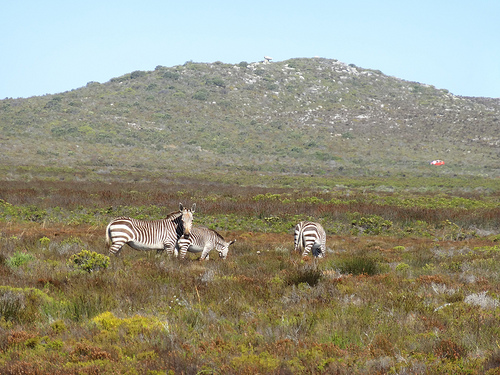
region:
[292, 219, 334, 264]
a zebra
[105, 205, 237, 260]
two zebras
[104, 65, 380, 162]
a mountain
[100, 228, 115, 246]
the zebras tail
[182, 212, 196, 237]
the zebras face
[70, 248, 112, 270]
a green bush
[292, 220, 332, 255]
zebra is black and white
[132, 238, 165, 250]
the zebras belly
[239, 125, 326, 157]
green bushes on the mountain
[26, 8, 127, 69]
a blue sky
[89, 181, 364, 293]
Three zebras in the foreground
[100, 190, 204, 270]
A side view of a zebra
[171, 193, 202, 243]
Zebra is looking at the camera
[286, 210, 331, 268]
A back view of a zebra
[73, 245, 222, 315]
Zebra is standing in the tall grass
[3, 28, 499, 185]
A mountain in the background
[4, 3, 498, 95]
The sky is clear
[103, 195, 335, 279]
Zebra's stripes are black and white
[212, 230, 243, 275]
Zebra is eating grass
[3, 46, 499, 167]
Mountain is covered in plants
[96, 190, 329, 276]
Three zebras in a field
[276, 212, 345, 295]
Back of zebra eating grass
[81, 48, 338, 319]
Picture of zebra taken during the day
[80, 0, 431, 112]
Sky overhead is blue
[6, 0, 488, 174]
No clouds in the sky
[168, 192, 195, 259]
Zebra looking at camera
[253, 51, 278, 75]
A goat on the hill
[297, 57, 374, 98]
Rocks on the hill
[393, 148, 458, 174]
Something red and white in the distance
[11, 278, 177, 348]
Multicolored brush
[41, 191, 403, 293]
zebras grazing in a valley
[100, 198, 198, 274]
the zebra has his head up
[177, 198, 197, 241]
the head of the zebra is white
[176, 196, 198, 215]
the zebra's ears are facing forward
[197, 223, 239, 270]
the zebra has his nose in the grass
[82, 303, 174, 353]
the grass has yellow leaves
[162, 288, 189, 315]
white flowers are in the valley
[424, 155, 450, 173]
an orange vehicle is in the distance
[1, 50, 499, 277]
a hill is behind the zebras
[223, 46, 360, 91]
rocks are on the hilltop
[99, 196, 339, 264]
three zebras in the savanna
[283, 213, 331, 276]
zebra is eating from the ground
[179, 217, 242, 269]
zebra eats grass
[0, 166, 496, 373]
field is covered with grass of different colors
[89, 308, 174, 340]
light yellow plants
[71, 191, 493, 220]
plants are brown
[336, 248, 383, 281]
dark green grass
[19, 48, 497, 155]
a small mountain covered with vegetation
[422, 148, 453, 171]
a red car traveling on side of the mountain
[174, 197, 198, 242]
zebra has pointy ears